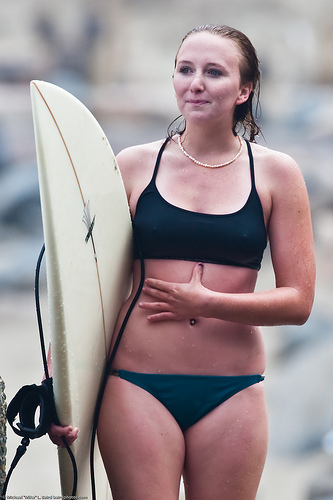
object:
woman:
[38, 21, 318, 498]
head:
[171, 25, 258, 128]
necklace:
[178, 130, 243, 168]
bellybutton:
[189, 318, 194, 327]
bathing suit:
[129, 137, 267, 271]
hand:
[137, 259, 203, 325]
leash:
[87, 259, 144, 500]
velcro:
[33, 404, 42, 430]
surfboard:
[29, 75, 137, 499]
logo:
[81, 199, 97, 246]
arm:
[203, 147, 316, 348]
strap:
[33, 244, 53, 381]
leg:
[185, 419, 270, 499]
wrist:
[205, 287, 221, 322]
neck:
[185, 110, 234, 148]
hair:
[172, 22, 267, 150]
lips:
[184, 96, 209, 106]